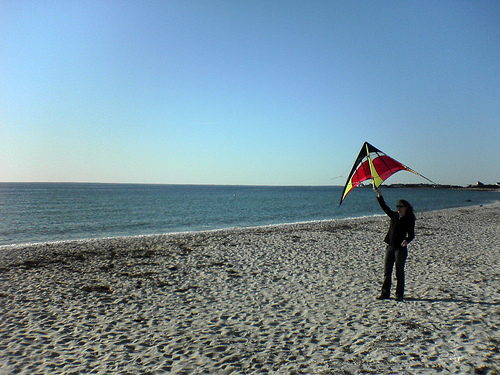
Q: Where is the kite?
A: In the woman's hand.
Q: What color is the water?
A: Blue.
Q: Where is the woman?
A: On a beach.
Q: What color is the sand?
A: Tan.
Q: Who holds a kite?
A: A woman.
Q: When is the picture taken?
A: Daytime.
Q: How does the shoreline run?
A: Diagonally.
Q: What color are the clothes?
A: Black.